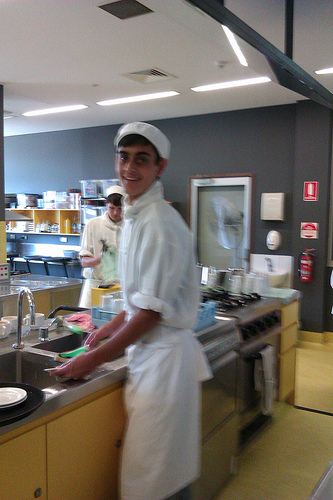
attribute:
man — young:
[50, 119, 207, 492]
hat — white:
[112, 118, 173, 158]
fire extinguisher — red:
[295, 246, 316, 281]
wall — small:
[293, 105, 322, 410]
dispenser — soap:
[263, 228, 284, 251]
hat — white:
[104, 183, 125, 199]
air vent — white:
[119, 65, 177, 84]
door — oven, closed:
[241, 323, 280, 437]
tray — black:
[3, 381, 45, 423]